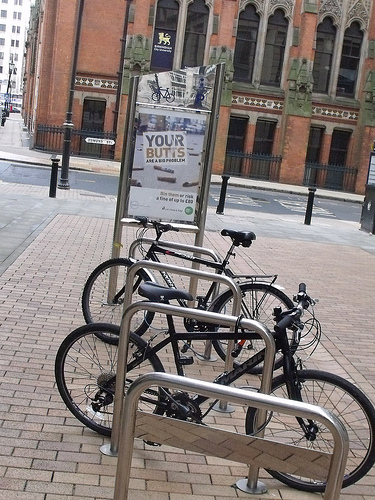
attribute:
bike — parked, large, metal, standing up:
[42, 277, 374, 492]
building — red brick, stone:
[25, 0, 373, 201]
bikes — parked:
[46, 228, 374, 499]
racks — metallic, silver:
[118, 236, 292, 484]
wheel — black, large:
[49, 316, 177, 441]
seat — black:
[129, 278, 196, 307]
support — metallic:
[101, 54, 235, 307]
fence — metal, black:
[42, 143, 329, 220]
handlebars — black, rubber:
[273, 276, 316, 332]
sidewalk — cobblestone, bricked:
[12, 185, 79, 321]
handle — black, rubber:
[265, 307, 302, 335]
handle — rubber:
[295, 275, 310, 300]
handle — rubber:
[125, 207, 153, 226]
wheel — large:
[239, 364, 374, 496]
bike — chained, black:
[78, 218, 319, 328]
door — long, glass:
[74, 90, 110, 156]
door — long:
[221, 108, 253, 177]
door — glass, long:
[298, 114, 324, 190]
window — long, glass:
[335, 17, 367, 105]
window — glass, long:
[308, 10, 338, 100]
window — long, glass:
[258, 6, 295, 91]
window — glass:
[228, 2, 264, 87]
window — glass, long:
[177, 4, 217, 67]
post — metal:
[42, 151, 63, 195]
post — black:
[295, 178, 323, 221]